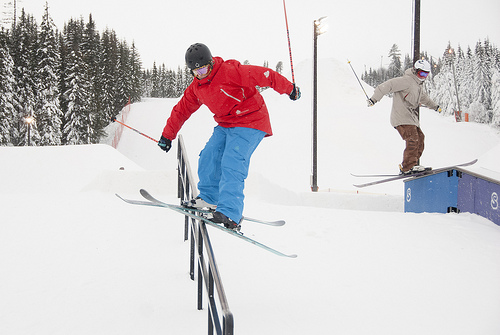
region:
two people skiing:
[98, 21, 466, 265]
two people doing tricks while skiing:
[70, 26, 495, 258]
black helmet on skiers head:
[180, 36, 219, 86]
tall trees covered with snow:
[16, 7, 127, 138]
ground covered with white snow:
[35, 198, 89, 285]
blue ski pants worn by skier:
[205, 117, 281, 227]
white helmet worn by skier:
[402, 48, 432, 88]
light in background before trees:
[15, 103, 43, 148]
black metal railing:
[167, 113, 230, 323]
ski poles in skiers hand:
[274, 4, 304, 114]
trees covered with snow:
[0, 1, 113, 93]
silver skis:
[115, 185, 307, 262]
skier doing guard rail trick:
[105, 42, 310, 269]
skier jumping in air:
[332, 40, 480, 211]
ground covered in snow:
[320, 218, 475, 328]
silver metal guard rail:
[187, 237, 242, 332]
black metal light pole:
[308, 40, 318, 197]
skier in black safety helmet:
[180, 36, 217, 81]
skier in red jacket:
[160, 46, 296, 153]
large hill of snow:
[319, 59, 349, 204]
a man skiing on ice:
[148, 39, 304, 245]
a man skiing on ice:
[353, 40, 448, 176]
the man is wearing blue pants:
[192, 125, 266, 232]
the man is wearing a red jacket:
[161, 55, 304, 143]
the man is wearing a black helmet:
[181, 37, 218, 76]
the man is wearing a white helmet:
[410, 57, 442, 78]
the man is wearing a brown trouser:
[396, 123, 433, 173]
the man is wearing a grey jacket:
[363, 71, 443, 127]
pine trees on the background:
[0, 0, 96, 145]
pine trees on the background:
[358, 36, 499, 126]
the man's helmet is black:
[166, 33, 244, 89]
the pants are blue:
[179, 106, 264, 251]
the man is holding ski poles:
[104, 3, 319, 193]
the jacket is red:
[151, 63, 296, 142]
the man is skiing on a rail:
[128, 33, 318, 256]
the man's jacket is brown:
[363, 63, 433, 125]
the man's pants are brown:
[393, 116, 427, 167]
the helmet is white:
[407, 53, 433, 83]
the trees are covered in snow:
[0, 16, 160, 151]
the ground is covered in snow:
[5, 138, 492, 331]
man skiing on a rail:
[122, 31, 322, 272]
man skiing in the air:
[342, 50, 478, 202]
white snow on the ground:
[258, 260, 498, 330]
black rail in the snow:
[184, 235, 241, 332]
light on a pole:
[302, 12, 339, 207]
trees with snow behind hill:
[2, 3, 126, 158]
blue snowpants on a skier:
[182, 120, 273, 220]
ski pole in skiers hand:
[97, 110, 159, 155]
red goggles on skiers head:
[414, 65, 437, 81]